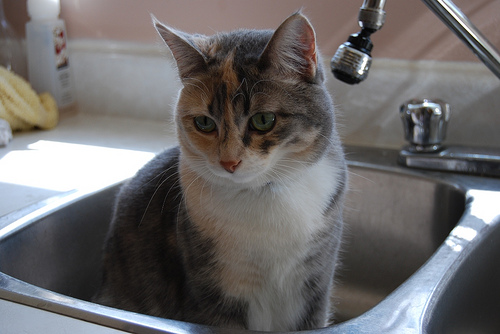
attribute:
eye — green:
[193, 112, 216, 134]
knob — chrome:
[392, 92, 450, 155]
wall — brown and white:
[74, 4, 151, 123]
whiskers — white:
[266, 156, 328, 191]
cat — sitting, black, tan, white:
[113, 16, 339, 323]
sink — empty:
[2, 160, 470, 333]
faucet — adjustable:
[332, 3, 500, 173]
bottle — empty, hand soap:
[23, 3, 78, 117]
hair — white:
[282, 35, 307, 82]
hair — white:
[167, 41, 194, 68]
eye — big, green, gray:
[245, 108, 284, 138]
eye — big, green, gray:
[190, 108, 222, 140]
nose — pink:
[219, 159, 245, 174]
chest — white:
[180, 160, 366, 297]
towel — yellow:
[2, 66, 63, 130]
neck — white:
[194, 164, 330, 199]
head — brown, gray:
[144, 17, 368, 185]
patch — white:
[176, 158, 343, 332]